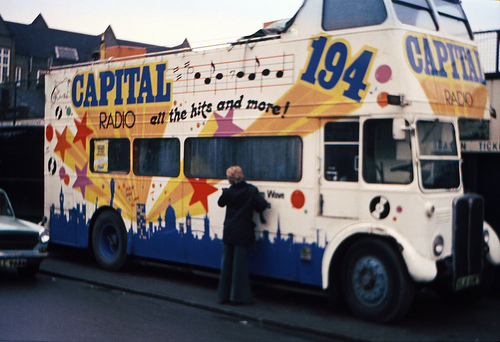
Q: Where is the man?
A: By the bus.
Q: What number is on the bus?
A: 194.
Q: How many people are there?
A: 1.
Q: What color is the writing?
A: Blue and yellow.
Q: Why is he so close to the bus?
A: Looking at it.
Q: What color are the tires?
A: Black.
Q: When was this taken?
A: During the day.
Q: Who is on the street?
A: The man.